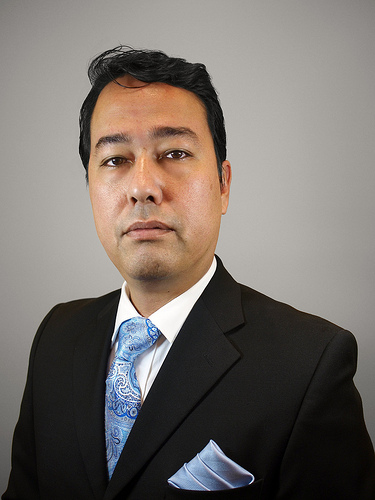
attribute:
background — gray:
[1, 0, 363, 498]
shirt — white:
[106, 254, 221, 477]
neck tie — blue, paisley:
[103, 315, 162, 478]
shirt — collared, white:
[104, 255, 217, 408]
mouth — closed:
[119, 218, 176, 241]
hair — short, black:
[77, 42, 229, 187]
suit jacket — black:
[0, 253, 363, 497]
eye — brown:
[156, 147, 194, 161]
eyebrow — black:
[147, 122, 199, 142]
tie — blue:
[103, 317, 160, 479]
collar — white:
[109, 255, 216, 349]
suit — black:
[1, 252, 363, 497]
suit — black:
[183, 356, 298, 421]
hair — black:
[83, 37, 171, 79]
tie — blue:
[68, 309, 180, 456]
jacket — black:
[100, 349, 285, 437]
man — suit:
[89, 51, 294, 350]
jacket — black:
[73, 326, 338, 469]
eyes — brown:
[77, 145, 215, 170]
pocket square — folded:
[154, 451, 222, 498]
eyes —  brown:
[94, 144, 195, 174]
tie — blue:
[102, 316, 159, 468]